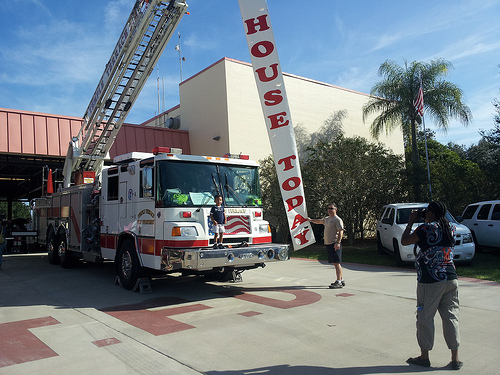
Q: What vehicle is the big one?
A: Fire truck.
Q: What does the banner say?
A: House today.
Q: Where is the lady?
A: In front of the truck.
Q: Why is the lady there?
A: To take a picture.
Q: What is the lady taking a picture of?
A: The truck.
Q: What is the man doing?
A: Holding the banner.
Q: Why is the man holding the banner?
A: To keep it up.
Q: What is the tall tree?
A: Palm.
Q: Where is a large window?
A: On the truck.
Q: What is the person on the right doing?
A: Taking a photo.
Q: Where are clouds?
A: In the sky.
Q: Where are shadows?
A: On the ground.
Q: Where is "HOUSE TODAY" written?
A: On a sign.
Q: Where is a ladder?
A: On the truck.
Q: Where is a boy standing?
A: On front of the truck.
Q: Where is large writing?
A: On the ground.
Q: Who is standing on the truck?
A: Little boy.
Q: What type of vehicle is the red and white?
A: Firetruck.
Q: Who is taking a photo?
A: Woman in dreads.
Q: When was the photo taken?
A: Daytime.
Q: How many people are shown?
A: Three.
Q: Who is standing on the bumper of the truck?
A: Child.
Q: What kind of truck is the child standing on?
A: Fire truck.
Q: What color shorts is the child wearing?
A: White.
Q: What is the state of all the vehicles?
A: Parked.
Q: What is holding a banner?
A: Ladder.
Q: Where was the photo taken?
A: A fire station.